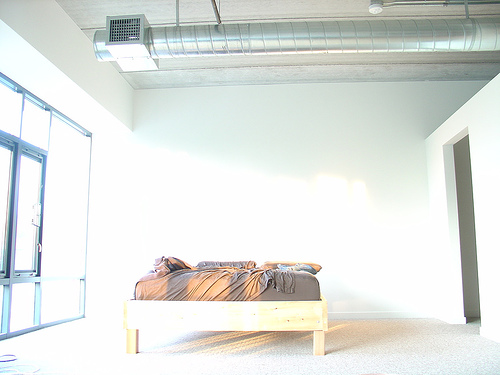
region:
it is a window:
[3, 79, 86, 329]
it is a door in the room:
[458, 126, 474, 327]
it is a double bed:
[135, 265, 323, 299]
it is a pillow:
[195, 261, 323, 273]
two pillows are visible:
[197, 256, 322, 271]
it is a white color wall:
[184, 107, 376, 219]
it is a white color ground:
[347, 321, 439, 370]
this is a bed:
[123, 250, 328, 330]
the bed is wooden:
[155, 300, 278, 329]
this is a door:
[440, 139, 475, 316]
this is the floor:
[345, 320, 409, 365]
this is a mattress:
[276, 270, 327, 297]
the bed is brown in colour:
[245, 304, 294, 326]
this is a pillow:
[265, 258, 317, 270]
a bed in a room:
[122, 256, 329, 358]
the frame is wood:
[124, 298, 328, 356]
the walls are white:
[0, 0, 497, 346]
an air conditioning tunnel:
[92, 15, 498, 72]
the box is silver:
[106, 18, 156, 71]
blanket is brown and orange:
[135, 255, 322, 300]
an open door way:
[442, 128, 480, 335]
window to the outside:
[0, 75, 84, 340]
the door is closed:
[1, 131, 43, 339]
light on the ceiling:
[367, 2, 383, 16]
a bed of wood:
[114, 246, 334, 356]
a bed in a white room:
[3, 8, 498, 373]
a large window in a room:
[0, 73, 105, 351]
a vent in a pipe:
[88, 8, 172, 80]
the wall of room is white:
[0, 80, 499, 366]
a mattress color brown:
[120, 240, 335, 361]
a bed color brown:
[118, 298, 334, 365]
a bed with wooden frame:
[131, 216, 331, 368]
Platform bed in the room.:
[130, 258, 334, 359]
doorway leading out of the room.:
[441, 137, 487, 334]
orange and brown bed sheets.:
[131, 258, 321, 302]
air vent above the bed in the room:
[101, 19, 159, 68]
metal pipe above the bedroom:
[93, 16, 498, 66]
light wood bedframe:
[125, 301, 330, 359]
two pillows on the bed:
[128, 248, 321, 300]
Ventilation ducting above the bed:
[92, 13, 499, 71]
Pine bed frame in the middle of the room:
[123, 296, 327, 356]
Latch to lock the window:
[37, 240, 42, 252]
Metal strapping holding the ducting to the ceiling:
[173, 0, 475, 58]